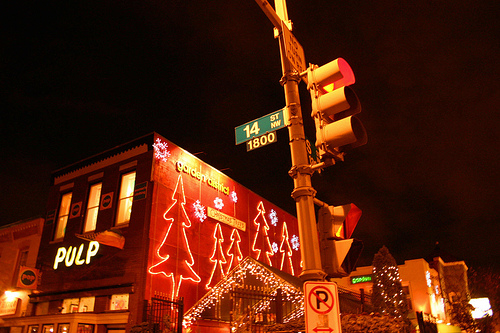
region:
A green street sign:
[221, 104, 288, 158]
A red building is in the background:
[38, 122, 324, 323]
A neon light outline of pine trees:
[148, 170, 289, 309]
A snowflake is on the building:
[151, 132, 176, 169]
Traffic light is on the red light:
[293, 51, 375, 173]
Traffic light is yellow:
[295, 49, 378, 170]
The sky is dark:
[6, 3, 241, 124]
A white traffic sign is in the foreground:
[296, 278, 356, 331]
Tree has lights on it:
[366, 240, 405, 322]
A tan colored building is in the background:
[341, 258, 461, 331]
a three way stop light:
[296, 52, 366, 172]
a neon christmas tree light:
[146, 171, 201, 313]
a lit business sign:
[48, 242, 100, 273]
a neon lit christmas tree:
[206, 221, 229, 292]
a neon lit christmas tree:
[223, 221, 243, 278]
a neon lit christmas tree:
[248, 197, 275, 273]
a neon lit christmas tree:
[276, 219, 295, 279]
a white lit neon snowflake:
[188, 197, 206, 222]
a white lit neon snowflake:
[208, 196, 227, 211]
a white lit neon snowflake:
[150, 134, 170, 163]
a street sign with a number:
[214, 98, 299, 153]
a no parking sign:
[292, 273, 350, 328]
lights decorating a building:
[150, 135, 298, 315]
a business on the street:
[4, 127, 179, 331]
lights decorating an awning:
[164, 256, 355, 323]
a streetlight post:
[297, 51, 373, 180]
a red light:
[311, 52, 371, 97]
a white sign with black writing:
[278, 15, 313, 78]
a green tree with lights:
[357, 239, 417, 331]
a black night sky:
[376, 17, 460, 127]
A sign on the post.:
[235, 106, 288, 152]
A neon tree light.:
[148, 167, 195, 312]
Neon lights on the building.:
[155, 161, 281, 318]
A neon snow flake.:
[150, 132, 172, 165]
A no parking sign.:
[301, 276, 343, 332]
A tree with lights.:
[370, 244, 410, 329]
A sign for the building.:
[12, 262, 43, 292]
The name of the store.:
[48, 237, 102, 268]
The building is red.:
[155, 175, 232, 294]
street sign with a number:
[207, 90, 297, 162]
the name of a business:
[32, 236, 132, 285]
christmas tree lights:
[150, 142, 209, 315]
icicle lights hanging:
[157, 258, 332, 323]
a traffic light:
[289, 39, 372, 163]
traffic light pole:
[263, 2, 356, 329]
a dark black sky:
[20, 19, 187, 100]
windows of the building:
[49, 159, 145, 243]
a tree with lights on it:
[363, 242, 422, 329]